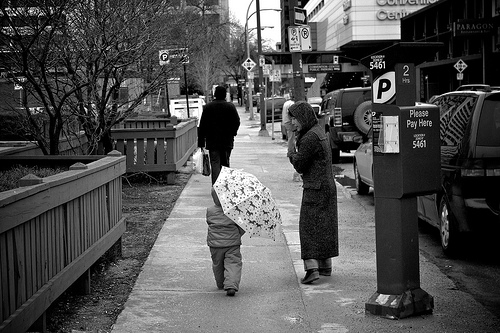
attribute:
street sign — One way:
[294, 10, 311, 22]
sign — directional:
[241, 56, 256, 73]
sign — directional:
[288, 25, 314, 53]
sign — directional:
[268, 67, 283, 83]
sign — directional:
[156, 47, 171, 69]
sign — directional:
[453, 59, 469, 74]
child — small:
[200, 184, 249, 297]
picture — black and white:
[0, 0, 500, 332]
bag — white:
[197, 152, 214, 177]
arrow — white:
[285, 33, 303, 45]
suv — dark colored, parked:
[393, 82, 496, 254]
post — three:
[104, 147, 121, 159]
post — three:
[68, 160, 90, 169]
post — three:
[19, 172, 41, 184]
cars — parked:
[271, 55, 482, 263]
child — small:
[205, 187, 242, 297]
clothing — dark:
[203, 101, 237, 162]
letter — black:
[376, 78, 391, 100]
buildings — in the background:
[261, 0, 499, 122]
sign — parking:
[370, 71, 399, 107]